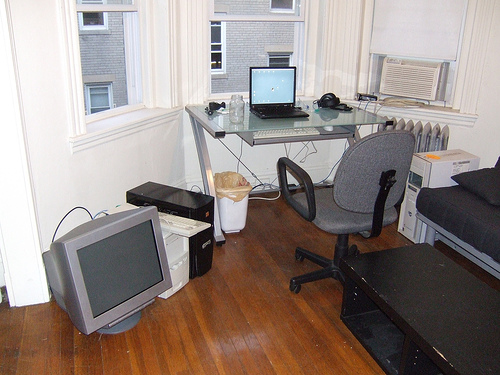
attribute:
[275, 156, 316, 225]
handle — black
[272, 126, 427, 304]
chair — office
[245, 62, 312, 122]
laptop — black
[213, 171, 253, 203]
bag — brown, plastic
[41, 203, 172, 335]
monitor — computer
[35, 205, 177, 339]
monitor — large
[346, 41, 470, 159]
heater — gray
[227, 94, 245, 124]
jar — empty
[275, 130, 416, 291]
chair — black, grey, office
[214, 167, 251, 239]
garbage can — white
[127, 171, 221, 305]
computers — old, unplugged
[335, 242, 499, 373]
table — black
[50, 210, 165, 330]
monitor — old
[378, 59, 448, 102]
air conditioner — white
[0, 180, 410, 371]
floor — wooden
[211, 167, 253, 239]
can — white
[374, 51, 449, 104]
unit — small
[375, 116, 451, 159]
radiator — gray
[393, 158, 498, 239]
sofa — black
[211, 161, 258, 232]
can — white, garbage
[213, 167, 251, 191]
bag — grocery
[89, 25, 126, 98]
building — brick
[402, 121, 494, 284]
tower — computer, white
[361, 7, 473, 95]
blinds — window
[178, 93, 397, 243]
desk — computer